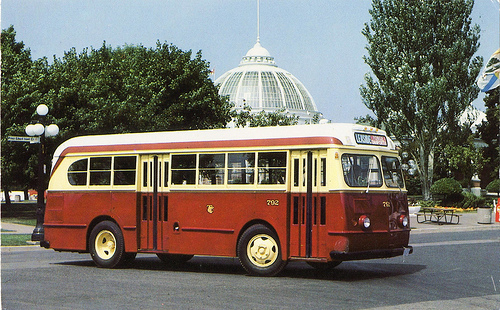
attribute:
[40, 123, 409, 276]
bus — parked, here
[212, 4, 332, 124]
dome — white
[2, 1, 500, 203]
tree — growing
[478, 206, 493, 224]
garbage can — here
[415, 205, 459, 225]
picnic table — here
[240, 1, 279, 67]
top — circular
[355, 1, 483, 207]
tree — tall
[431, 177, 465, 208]
bush — round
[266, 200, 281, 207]
number — yellow